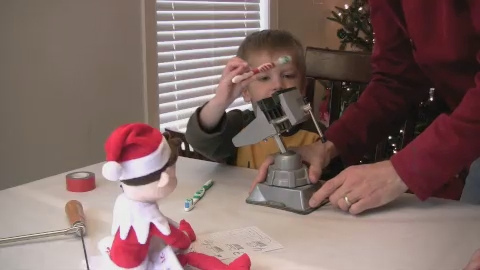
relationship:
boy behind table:
[185, 29, 327, 167] [0, 154, 479, 269]